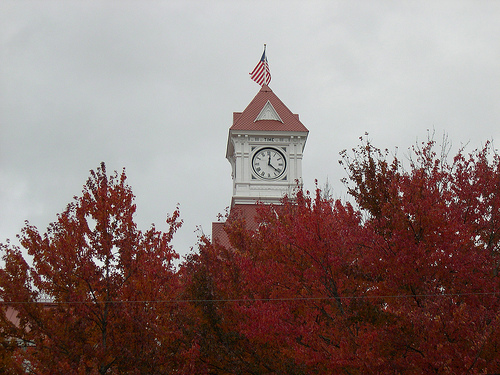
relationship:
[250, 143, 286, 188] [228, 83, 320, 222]
clock on building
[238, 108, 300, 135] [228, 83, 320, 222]
roof on building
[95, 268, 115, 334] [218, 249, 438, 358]
branch on tree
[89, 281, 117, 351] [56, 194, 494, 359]
branches on trees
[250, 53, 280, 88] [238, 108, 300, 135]
flag on roof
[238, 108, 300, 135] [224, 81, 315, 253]
roof on tower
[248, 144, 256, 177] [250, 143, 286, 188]
border on clock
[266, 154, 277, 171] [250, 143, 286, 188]
hands on clock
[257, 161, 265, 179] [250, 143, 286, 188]
numbers on clock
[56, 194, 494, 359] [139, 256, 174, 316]
trees have leaves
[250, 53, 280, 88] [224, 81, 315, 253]
flag on tower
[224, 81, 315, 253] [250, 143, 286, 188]
tower has clock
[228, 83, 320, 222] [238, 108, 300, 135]
building has roof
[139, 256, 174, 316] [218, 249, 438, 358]
leaves on tree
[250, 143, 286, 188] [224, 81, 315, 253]
clock on tower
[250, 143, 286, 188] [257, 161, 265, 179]
clock has numbers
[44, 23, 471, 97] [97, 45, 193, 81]
sky has cloud